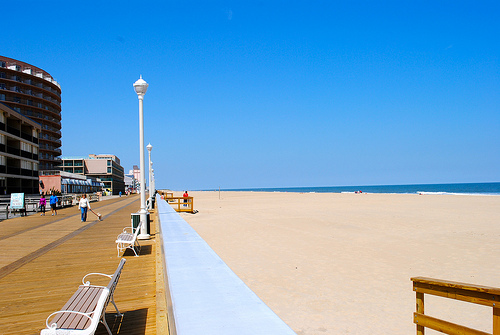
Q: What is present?
A: A beach.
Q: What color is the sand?
A: Brown.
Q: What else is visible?
A: Buildings.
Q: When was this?
A: Daytime.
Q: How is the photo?
A: Clear.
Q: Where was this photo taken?
A: At a beach.